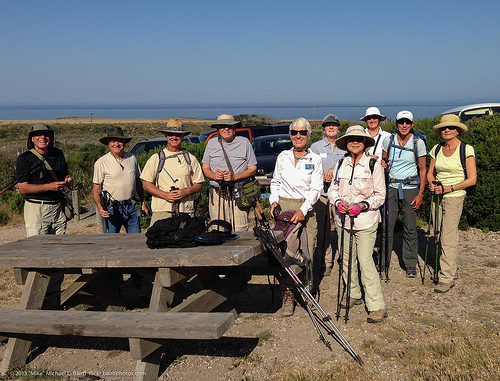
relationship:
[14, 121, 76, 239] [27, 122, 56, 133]
man wearing hat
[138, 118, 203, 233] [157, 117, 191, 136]
man wearing hat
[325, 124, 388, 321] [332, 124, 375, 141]
woman wearing hat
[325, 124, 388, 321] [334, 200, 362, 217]
woman wearing gloves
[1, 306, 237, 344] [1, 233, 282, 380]
seat on table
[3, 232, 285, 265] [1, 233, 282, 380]
top of table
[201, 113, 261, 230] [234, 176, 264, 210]
man carrying bag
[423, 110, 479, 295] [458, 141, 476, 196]
people wearing backpack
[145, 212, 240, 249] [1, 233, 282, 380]
bag on table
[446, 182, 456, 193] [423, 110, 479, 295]
watch on people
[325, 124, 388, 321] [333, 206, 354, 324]
woman holding poles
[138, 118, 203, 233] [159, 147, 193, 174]
man with backback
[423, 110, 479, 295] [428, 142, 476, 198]
people wearing shirt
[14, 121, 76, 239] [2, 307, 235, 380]
man near bench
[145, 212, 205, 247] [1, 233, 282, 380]
bag on table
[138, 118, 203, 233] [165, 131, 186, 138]
man wearing glasses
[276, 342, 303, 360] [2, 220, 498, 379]
gravel on ground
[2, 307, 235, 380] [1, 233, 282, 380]
bench of table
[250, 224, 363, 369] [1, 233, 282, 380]
poles on table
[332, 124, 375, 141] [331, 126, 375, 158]
hat on head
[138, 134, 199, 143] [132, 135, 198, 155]
roof of car